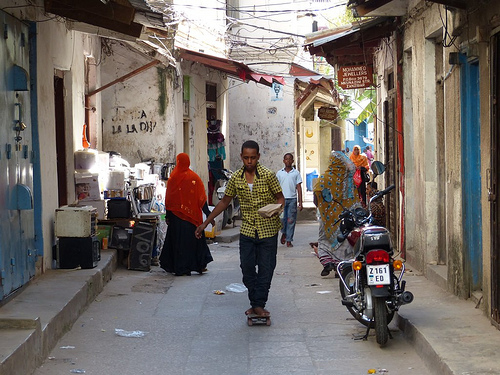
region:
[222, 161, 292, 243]
yellow and black shirt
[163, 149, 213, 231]
woman with red scraf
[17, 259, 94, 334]
small narrow side walk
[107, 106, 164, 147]
black graffiti on white wall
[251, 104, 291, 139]
dirty wall in the street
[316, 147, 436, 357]
bike parked near the side walk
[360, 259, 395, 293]
white and black license plate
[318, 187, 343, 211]
circle rear view mirror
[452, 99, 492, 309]
light blue painted door trim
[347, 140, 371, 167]
woman with orange scraf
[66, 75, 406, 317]
a busy tight street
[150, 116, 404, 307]
people walking in the area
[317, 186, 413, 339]
a motorcycle bike on the curb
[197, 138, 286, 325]
this kid is riding a skateboard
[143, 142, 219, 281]
this lady is wearing orange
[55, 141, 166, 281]
a pile of material next to the building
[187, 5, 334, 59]
wires above the street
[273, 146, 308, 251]
a yooung man in a blue shirt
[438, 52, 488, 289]
a blue doorway to this building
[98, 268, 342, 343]
trash on the streets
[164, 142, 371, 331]
people in paved ally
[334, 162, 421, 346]
back of parked motorbike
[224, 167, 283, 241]
yellow and black checkered shirt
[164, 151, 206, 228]
back of red fabric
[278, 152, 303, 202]
man in white shirt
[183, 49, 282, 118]
red awning over doorway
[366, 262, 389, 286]
white square license plate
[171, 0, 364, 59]
electric wires suspended in air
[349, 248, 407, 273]
yellow and red lights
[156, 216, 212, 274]
long dress on legs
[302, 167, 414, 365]
the bike is parked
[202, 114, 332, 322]
boy riding a skateboard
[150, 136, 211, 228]
the jihab is red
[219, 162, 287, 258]
the shirt is checkered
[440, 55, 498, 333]
the door is blue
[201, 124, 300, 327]
the boy is carrying a book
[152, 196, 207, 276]
the dress is black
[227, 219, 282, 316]
the pants are black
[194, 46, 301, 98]
the roof is red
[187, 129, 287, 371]
a boy on skateboard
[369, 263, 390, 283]
The silver plate with "Z161 ED" printed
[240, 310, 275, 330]
The skateboard the boy uses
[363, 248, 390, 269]
The red stoplight on a motorcycle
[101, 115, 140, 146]
"La La" is written on the side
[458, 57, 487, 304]
A blue door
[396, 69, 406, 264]
A red pole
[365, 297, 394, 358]
A back tire of a motorcycle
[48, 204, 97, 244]
A beige box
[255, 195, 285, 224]
A package being held by the boy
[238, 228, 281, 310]
The boy's dark pants used.